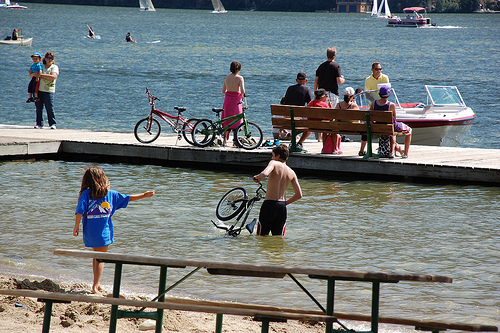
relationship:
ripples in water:
[163, 222, 201, 251] [346, 185, 498, 268]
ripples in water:
[0, 160, 500, 333] [293, 210, 330, 257]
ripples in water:
[0, 160, 500, 333] [6, 165, 38, 236]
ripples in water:
[0, 160, 500, 333] [172, 17, 289, 57]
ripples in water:
[215, 276, 274, 297] [362, 32, 497, 72]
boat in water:
[272, 83, 477, 146] [48, 9, 492, 261]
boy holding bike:
[252, 144, 303, 236] [216, 176, 267, 235]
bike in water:
[211, 177, 267, 237] [7, 153, 499, 314]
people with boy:
[34, 52, 60, 130] [24, 49, 44, 108]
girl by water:
[73, 167, 156, 295] [3, 0, 497, 147]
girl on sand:
[73, 167, 156, 295] [1, 275, 392, 330]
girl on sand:
[73, 167, 156, 295] [1, 288, 148, 326]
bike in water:
[212, 166, 276, 242] [7, 153, 499, 314]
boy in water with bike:
[253, 144, 302, 236] [211, 177, 276, 239]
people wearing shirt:
[34, 52, 60, 130] [37, 66, 62, 91]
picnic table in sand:
[0, 248, 499, 333] [10, 277, 355, 330]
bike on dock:
[134, 87, 209, 146] [0, 121, 499, 187]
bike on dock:
[191, 93, 263, 150] [0, 121, 499, 187]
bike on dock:
[129, 86, 198, 143] [0, 121, 499, 187]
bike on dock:
[191, 99, 266, 149] [0, 121, 499, 187]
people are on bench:
[275, 67, 312, 157] [269, 100, 399, 151]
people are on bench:
[304, 86, 344, 152] [269, 100, 399, 151]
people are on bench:
[333, 83, 372, 155] [269, 100, 399, 151]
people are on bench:
[367, 85, 412, 159] [269, 100, 399, 151]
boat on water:
[317, 87, 479, 144] [4, 0, 494, 319]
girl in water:
[62, 160, 139, 303] [4, 145, 499, 331]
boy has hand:
[253, 144, 302, 236] [283, 193, 297, 208]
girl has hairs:
[73, 167, 156, 295] [82, 165, 127, 190]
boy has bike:
[253, 144, 302, 236] [211, 177, 267, 237]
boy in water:
[253, 144, 302, 236] [7, 153, 499, 314]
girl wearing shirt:
[73, 167, 156, 295] [79, 188, 133, 246]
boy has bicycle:
[253, 144, 302, 236] [199, 172, 270, 227]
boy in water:
[253, 144, 302, 236] [4, 145, 499, 331]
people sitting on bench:
[284, 72, 312, 150] [266, 99, 397, 156]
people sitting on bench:
[307, 88, 344, 154] [266, 99, 397, 156]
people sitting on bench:
[334, 87, 366, 156] [266, 99, 397, 156]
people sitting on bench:
[369, 85, 413, 158] [266, 99, 397, 156]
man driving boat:
[363, 51, 394, 105] [312, 78, 473, 155]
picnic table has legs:
[2, 242, 498, 331] [37, 276, 384, 331]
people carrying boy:
[34, 52, 60, 130] [26, 52, 43, 103]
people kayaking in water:
[80, 21, 104, 44] [23, 5, 233, 66]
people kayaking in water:
[118, 29, 152, 47] [23, 5, 233, 66]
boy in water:
[253, 144, 302, 236] [127, 160, 465, 268]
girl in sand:
[73, 167, 156, 295] [2, 276, 327, 330]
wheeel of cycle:
[216, 187, 248, 219] [211, 177, 265, 237]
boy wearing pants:
[253, 144, 302, 236] [258, 198, 288, 239]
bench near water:
[263, 104, 398, 151] [332, 159, 440, 239]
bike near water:
[191, 93, 263, 150] [9, 156, 490, 328]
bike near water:
[134, 87, 209, 146] [9, 156, 490, 328]